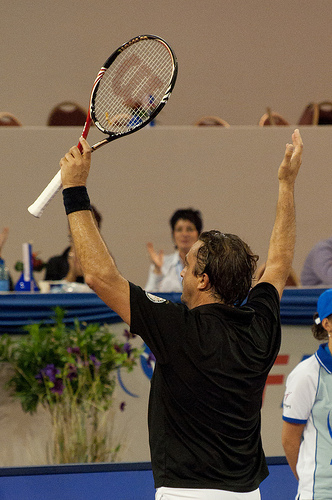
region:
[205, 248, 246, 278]
wet dark brown hair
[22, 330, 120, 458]
a plant in front of the man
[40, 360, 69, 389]
purple blooms on the plant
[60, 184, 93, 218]
a black band on a wrist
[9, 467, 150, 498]
a low blue wall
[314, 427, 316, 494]
a thin blue stripe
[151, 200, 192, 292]
a woman clapping her hands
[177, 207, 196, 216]
black hair on a head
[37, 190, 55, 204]
white handle of a tennis racket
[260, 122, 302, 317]
an arm raised into the air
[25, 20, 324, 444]
guy holding tennis racquet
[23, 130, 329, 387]
guy with both arms raised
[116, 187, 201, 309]
lady clapping her hands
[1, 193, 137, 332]
person wearing black top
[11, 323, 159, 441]
purple flowers and green leaves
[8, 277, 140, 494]
blue and white facing and trim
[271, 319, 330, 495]
blue and white shirt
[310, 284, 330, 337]
blue cap with white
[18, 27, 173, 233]
white handle on tennis racquet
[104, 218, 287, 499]
guy wearing black shirt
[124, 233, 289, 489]
back of man in black shirt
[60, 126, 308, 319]
two raised hands of man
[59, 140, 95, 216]
black band on wrist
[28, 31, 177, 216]
racket with white grip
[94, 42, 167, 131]
white string of racket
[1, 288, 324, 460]
wall with blue material on top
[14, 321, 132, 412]
green leaves and purple flowers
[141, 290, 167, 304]
white round sleeve patch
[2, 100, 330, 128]
tops of empty chairs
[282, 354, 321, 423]
white sleeve with blue trim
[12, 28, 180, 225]
A man holding a tennis racket.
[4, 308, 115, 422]
Flowers outside the court.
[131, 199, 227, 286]
The judge is clapping.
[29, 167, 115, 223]
The tennis player is wearing a wristband.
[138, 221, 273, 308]
The man is very sweaty.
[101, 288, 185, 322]
A round white patch on the sleeve.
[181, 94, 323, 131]
Empty chairs for guest.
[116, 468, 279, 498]
White shorts on the player.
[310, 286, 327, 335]
The official is wearing a blue hat.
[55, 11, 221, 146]
A name brand tennis racket.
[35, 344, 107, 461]
Purple and yellow flowers by a counter.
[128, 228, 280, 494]
Man wearing black wrinkled shirt.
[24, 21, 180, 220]
A red and white tennis racket.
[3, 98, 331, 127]
A row of brown chairs.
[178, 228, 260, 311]
A man with wet matted hair.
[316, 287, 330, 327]
A chalk blue baseball cap.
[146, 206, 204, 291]
A woman with her hand in the air.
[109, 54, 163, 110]
The letter W on a tennis racket.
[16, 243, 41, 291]
A blue bottle of imported water.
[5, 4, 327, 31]
A plain beige painted wall.